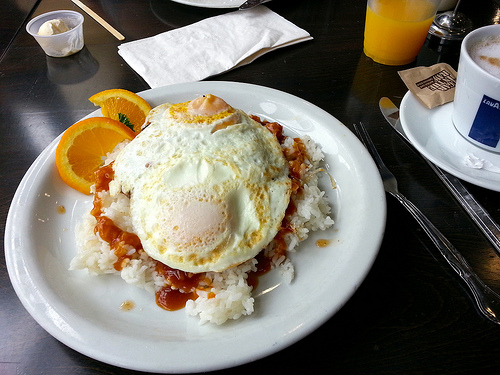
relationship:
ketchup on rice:
[95, 114, 306, 309] [70, 115, 337, 324]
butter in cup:
[36, 17, 80, 55] [26, 9, 85, 60]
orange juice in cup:
[363, 3, 436, 66] [365, 1, 442, 70]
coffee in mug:
[469, 33, 500, 77] [454, 25, 500, 153]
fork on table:
[350, 119, 499, 323] [4, 4, 494, 368]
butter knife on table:
[377, 96, 500, 246] [4, 4, 494, 368]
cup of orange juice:
[365, 1, 442, 70] [363, 3, 436, 66]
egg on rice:
[105, 92, 293, 273] [70, 115, 337, 324]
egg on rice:
[130, 147, 293, 272] [70, 115, 337, 324]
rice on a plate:
[70, 115, 337, 324] [2, 80, 388, 373]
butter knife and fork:
[377, 96, 500, 246] [350, 119, 499, 323]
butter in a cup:
[36, 17, 80, 55] [26, 9, 85, 60]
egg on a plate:
[105, 92, 293, 273] [2, 80, 388, 373]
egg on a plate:
[130, 147, 293, 272] [2, 80, 388, 373]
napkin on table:
[117, 5, 312, 90] [4, 4, 494, 368]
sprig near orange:
[116, 112, 136, 131] [56, 115, 139, 195]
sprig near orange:
[116, 112, 136, 131] [89, 87, 152, 136]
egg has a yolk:
[105, 92, 293, 273] [169, 93, 237, 124]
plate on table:
[2, 80, 388, 373] [4, 4, 494, 368]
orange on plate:
[56, 115, 139, 195] [2, 80, 388, 373]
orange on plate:
[89, 87, 152, 136] [2, 80, 388, 373]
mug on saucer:
[454, 25, 500, 153] [397, 87, 497, 190]